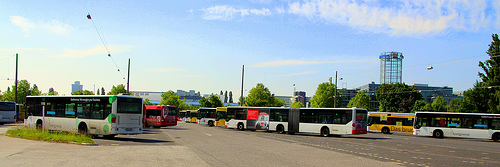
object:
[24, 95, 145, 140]
bus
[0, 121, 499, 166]
lot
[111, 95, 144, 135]
back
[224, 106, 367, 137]
bus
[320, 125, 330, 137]
wheel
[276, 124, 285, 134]
wheel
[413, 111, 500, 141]
bus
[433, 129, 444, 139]
wheel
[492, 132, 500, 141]
wheel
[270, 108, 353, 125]
windows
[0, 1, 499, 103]
sky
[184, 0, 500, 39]
cloud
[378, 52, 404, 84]
building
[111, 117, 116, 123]
tail light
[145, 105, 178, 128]
bus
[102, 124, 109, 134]
marking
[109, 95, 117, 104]
marking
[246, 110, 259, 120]
panel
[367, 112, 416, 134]
bus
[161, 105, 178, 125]
back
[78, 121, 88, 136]
wheel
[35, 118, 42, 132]
wheel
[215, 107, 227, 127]
bus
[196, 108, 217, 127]
bus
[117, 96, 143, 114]
window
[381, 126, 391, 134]
wheel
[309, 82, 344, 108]
tree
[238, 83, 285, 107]
tree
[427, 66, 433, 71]
balloon